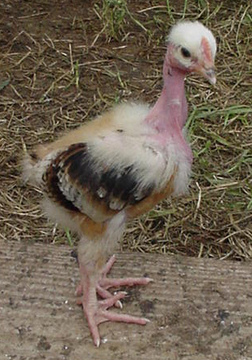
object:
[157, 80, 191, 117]
neck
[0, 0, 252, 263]
grass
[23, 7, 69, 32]
mud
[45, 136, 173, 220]
feathers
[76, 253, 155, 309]
claw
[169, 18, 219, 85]
head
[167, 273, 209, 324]
mat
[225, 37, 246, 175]
straw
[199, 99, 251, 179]
hay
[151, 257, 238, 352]
floor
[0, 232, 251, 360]
plank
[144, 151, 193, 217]
chest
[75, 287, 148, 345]
feet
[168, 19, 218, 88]
face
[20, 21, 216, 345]
animal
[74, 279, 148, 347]
claw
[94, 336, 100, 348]
nail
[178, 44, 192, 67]
eye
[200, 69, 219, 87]
beak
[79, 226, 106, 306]
legs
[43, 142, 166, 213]
wing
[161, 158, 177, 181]
part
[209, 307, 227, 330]
part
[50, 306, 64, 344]
part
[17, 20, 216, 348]
body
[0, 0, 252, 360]
ground